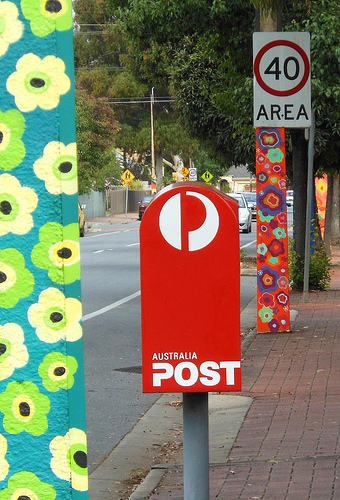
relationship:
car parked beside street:
[133, 194, 156, 221] [80, 219, 255, 477]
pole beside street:
[144, 83, 158, 185] [80, 219, 255, 477]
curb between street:
[126, 466, 170, 500] [80, 219, 255, 477]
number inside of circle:
[262, 53, 301, 82] [253, 39, 311, 99]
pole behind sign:
[301, 104, 319, 298] [248, 25, 316, 131]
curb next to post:
[126, 466, 170, 500] [1, 0, 93, 499]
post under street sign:
[123, 182, 133, 217] [116, 167, 137, 190]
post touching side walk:
[250, 122, 293, 340] [148, 259, 339, 500]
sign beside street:
[135, 181, 247, 400] [80, 219, 255, 477]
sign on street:
[248, 25, 316, 131] [80, 219, 255, 477]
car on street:
[222, 189, 255, 237] [80, 219, 255, 477]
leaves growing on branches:
[185, 51, 212, 78] [164, 23, 252, 87]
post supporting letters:
[178, 391, 214, 499] [253, 102, 309, 125]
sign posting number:
[248, 25, 316, 131] [262, 53, 301, 82]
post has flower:
[1, 0, 93, 499] [29, 220, 84, 288]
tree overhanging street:
[97, 0, 339, 288] [80, 219, 255, 477]